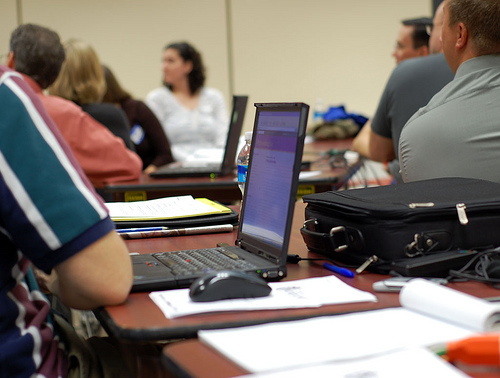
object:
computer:
[101, 101, 311, 295]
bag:
[299, 167, 498, 288]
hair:
[163, 40, 205, 95]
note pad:
[195, 277, 499, 376]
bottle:
[310, 97, 324, 124]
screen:
[240, 108, 298, 245]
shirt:
[0, 65, 123, 377]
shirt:
[138, 81, 232, 179]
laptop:
[122, 95, 308, 298]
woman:
[39, 29, 176, 173]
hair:
[42, 36, 108, 103]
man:
[0, 21, 143, 188]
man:
[0, 73, 136, 377]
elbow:
[78, 247, 135, 311]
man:
[367, 0, 469, 162]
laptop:
[145, 91, 252, 179]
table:
[94, 160, 252, 202]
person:
[392, 0, 499, 188]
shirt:
[392, 54, 499, 185]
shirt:
[370, 51, 457, 154]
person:
[350, 16, 453, 162]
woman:
[130, 41, 238, 163]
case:
[297, 176, 500, 281]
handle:
[299, 216, 349, 253]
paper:
[105, 195, 235, 227]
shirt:
[0, 60, 146, 190]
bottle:
[236, 132, 254, 204]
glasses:
[423, 19, 447, 37]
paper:
[194, 277, 500, 372]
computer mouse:
[188, 272, 273, 302]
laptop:
[108, 84, 297, 285]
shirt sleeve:
[0, 71, 120, 277]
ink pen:
[323, 262, 355, 279]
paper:
[155, 269, 378, 319]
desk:
[90, 193, 500, 364]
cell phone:
[372, 275, 449, 293]